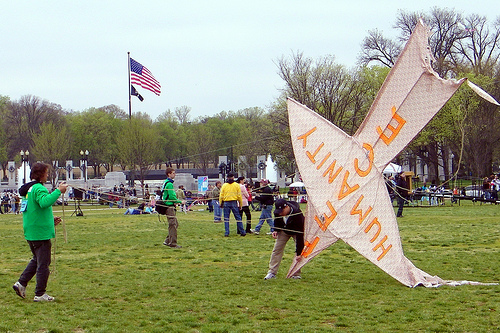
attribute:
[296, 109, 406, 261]
lettering — orange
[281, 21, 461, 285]
kite — white, large, orange, huge, beige, big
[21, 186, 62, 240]
jacket — green, yellow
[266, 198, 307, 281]
man — bending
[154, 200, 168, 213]
case — black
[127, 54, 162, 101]
flags — flying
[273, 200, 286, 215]
hat — black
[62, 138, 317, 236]
string — white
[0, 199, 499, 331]
ground — grassy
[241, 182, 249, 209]
sweater — pink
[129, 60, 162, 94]
flag — red, blue, white, american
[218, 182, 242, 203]
jacket — yellow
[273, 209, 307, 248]
jacket — black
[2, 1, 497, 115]
sky — light blue, clear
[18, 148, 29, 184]
light pole — black, white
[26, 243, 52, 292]
pants — grey, gray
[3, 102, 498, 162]
trees — green